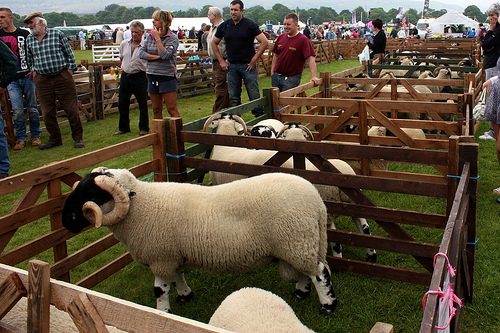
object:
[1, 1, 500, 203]
people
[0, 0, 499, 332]
fair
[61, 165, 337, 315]
ram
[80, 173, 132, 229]
horns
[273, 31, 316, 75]
shirt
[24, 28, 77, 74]
shirt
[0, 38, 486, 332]
enclosures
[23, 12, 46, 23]
hat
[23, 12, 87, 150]
man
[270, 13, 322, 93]
man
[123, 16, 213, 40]
tent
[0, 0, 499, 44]
background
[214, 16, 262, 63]
shirt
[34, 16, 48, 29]
hair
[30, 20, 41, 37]
beard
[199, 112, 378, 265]
sheep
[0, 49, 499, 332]
grass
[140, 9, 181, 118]
woman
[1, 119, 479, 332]
enclosure